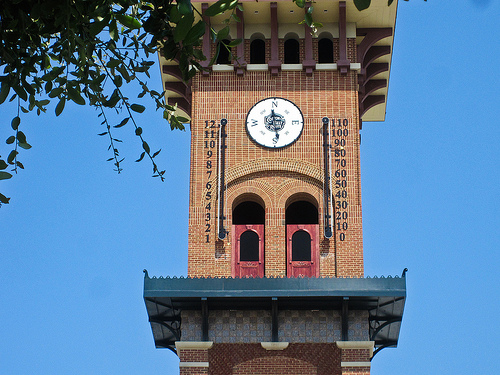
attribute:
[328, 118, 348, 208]
number — black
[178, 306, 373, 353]
white wall — white textured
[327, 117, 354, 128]
number — black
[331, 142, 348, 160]
number — black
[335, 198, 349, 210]
number — black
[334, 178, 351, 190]
number — black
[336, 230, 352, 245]
number — black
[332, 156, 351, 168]
number — black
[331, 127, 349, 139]
number — black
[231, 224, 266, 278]
door — red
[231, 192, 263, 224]
window — arched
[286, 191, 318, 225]
window — arched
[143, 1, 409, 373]
tower — red, bricked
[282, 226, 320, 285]
door — red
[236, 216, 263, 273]
door — red